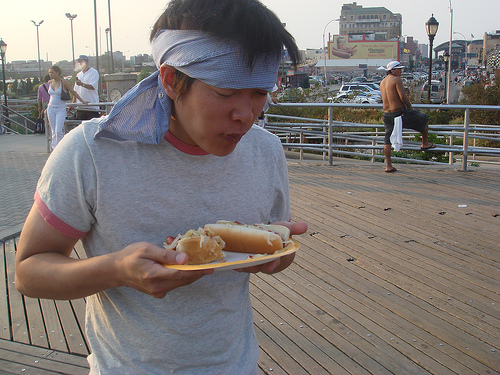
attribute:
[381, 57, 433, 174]
man — standing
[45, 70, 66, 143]
woman — standing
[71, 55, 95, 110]
man — standing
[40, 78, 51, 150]
woman — standing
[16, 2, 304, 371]
man — standing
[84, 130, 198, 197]
shirt — grey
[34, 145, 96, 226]
sleeve — short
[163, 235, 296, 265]
plate — paper, round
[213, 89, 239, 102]
eye — closed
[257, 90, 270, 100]
eye — closed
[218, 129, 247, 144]
mouth — closed